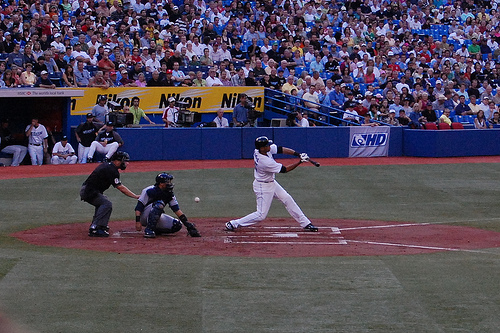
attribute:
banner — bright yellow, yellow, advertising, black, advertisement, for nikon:
[55, 87, 266, 116]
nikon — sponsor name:
[159, 93, 202, 113]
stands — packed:
[1, 2, 499, 129]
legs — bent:
[6, 144, 26, 168]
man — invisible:
[0, 119, 26, 167]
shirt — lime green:
[126, 107, 145, 126]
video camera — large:
[176, 100, 202, 126]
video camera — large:
[106, 98, 135, 129]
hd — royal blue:
[367, 132, 388, 148]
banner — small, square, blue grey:
[349, 125, 391, 157]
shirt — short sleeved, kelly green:
[464, 46, 482, 52]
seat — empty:
[455, 117, 473, 129]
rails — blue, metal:
[262, 89, 393, 129]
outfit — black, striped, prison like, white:
[173, 19, 189, 37]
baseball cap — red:
[165, 68, 172, 75]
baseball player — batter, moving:
[226, 137, 319, 232]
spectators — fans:
[2, 1, 499, 129]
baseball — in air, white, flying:
[193, 196, 201, 205]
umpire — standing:
[78, 151, 142, 237]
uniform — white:
[231, 144, 311, 230]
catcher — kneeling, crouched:
[135, 173, 201, 239]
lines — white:
[226, 220, 494, 258]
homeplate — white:
[270, 231, 297, 239]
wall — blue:
[78, 126, 500, 160]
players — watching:
[0, 113, 121, 166]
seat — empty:
[412, 29, 427, 36]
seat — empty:
[425, 28, 438, 40]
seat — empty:
[443, 28, 449, 38]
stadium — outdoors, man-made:
[0, 1, 499, 166]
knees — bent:
[98, 201, 113, 213]